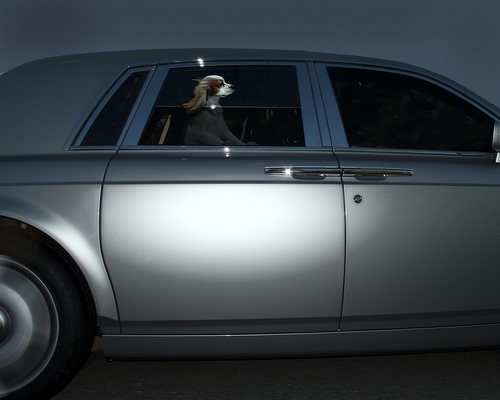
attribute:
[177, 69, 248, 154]
dog — brown, white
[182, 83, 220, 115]
ears — fluffy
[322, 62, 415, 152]
window — narrow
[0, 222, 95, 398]
black tire — rubber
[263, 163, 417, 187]
handles — oval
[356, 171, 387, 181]
handle — silver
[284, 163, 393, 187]
handle — silver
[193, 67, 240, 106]
dog head — brown, white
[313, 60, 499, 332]
door — gray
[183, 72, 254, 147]
dog — white, brown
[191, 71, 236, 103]
head — brown, white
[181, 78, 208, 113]
hair — long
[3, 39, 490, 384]
car — silver, grey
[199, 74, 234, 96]
head — dog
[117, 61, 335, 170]
window — lowered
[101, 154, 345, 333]
door — rear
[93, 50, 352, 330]
door — rear